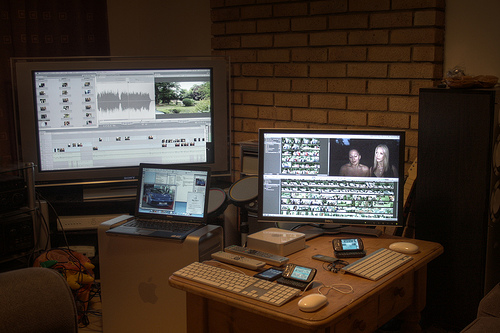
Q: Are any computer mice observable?
A: Yes, there is a computer mouse.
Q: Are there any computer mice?
A: Yes, there is a computer mouse.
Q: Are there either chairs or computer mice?
A: Yes, there is a computer mouse.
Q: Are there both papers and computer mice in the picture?
A: No, there is a computer mouse but no papers.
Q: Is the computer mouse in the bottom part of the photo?
A: Yes, the computer mouse is in the bottom of the image.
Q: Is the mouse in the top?
A: No, the mouse is in the bottom of the image.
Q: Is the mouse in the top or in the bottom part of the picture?
A: The mouse is in the bottom of the image.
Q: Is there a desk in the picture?
A: Yes, there is a desk.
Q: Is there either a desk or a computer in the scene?
A: Yes, there is a desk.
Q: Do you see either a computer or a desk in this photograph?
A: Yes, there is a desk.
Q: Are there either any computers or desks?
A: Yes, there is a desk.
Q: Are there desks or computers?
A: Yes, there is a desk.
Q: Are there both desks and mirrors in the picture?
A: No, there is a desk but no mirrors.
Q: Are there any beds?
A: No, there are no beds.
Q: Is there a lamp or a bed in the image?
A: No, there are no beds or lamps.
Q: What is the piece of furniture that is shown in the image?
A: The piece of furniture is a desk.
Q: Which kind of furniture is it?
A: The piece of furniture is a desk.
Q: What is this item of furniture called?
A: That is a desk.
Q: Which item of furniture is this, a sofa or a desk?
A: That is a desk.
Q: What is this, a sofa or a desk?
A: This is a desk.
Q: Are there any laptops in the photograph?
A: Yes, there is a laptop.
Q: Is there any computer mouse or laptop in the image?
A: Yes, there is a laptop.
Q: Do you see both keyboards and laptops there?
A: Yes, there are both a laptop and a keyboard.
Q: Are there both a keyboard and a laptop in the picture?
A: Yes, there are both a laptop and a keyboard.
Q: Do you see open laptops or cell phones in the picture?
A: Yes, there is an open laptop.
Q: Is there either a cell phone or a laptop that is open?
A: Yes, the laptop is open.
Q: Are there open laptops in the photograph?
A: Yes, there is an open laptop.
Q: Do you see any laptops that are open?
A: Yes, there is a laptop that is open.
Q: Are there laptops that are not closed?
A: Yes, there is a open laptop.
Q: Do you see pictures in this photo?
A: No, there are no pictures.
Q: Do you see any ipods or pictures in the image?
A: No, there are no pictures or ipods.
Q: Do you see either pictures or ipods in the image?
A: No, there are no pictures or ipods.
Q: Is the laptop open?
A: Yes, the laptop is open.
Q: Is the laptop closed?
A: No, the laptop is open.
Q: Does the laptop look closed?
A: No, the laptop is open.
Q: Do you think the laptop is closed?
A: No, the laptop is open.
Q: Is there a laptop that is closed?
A: No, there is a laptop but it is open.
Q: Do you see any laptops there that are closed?
A: No, there is a laptop but it is open.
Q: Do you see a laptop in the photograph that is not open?
A: No, there is a laptop but it is open.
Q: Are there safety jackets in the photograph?
A: No, there are no safety jackets.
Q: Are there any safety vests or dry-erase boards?
A: No, there are no safety vests or dry-erase boards.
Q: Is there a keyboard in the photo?
A: Yes, there is a keyboard.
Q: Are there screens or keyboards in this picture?
A: Yes, there is a keyboard.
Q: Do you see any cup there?
A: No, there are no cups.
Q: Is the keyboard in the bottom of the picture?
A: Yes, the keyboard is in the bottom of the image.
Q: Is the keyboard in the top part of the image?
A: No, the keyboard is in the bottom of the image.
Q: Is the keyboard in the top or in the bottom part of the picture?
A: The keyboard is in the bottom of the image.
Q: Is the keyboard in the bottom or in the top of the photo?
A: The keyboard is in the bottom of the image.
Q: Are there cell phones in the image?
A: Yes, there is a cell phone.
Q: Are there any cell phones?
A: Yes, there is a cell phone.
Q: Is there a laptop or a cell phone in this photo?
A: Yes, there is a cell phone.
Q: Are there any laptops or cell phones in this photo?
A: Yes, there is a cell phone.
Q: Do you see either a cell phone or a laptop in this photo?
A: Yes, there is a cell phone.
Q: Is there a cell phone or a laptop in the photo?
A: Yes, there is a cell phone.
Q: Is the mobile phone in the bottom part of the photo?
A: Yes, the mobile phone is in the bottom of the image.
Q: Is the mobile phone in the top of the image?
A: No, the mobile phone is in the bottom of the image.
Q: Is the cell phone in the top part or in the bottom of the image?
A: The cell phone is in the bottom of the image.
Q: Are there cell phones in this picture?
A: Yes, there is a cell phone.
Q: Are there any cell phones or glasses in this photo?
A: Yes, there is a cell phone.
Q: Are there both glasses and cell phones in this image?
A: No, there is a cell phone but no glasses.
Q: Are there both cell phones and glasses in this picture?
A: No, there is a cell phone but no glasses.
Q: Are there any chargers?
A: No, there are no chargers.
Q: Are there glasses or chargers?
A: No, there are no chargers or glasses.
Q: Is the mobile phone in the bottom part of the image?
A: Yes, the mobile phone is in the bottom of the image.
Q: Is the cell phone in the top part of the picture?
A: No, the cell phone is in the bottom of the image.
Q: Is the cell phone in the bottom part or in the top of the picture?
A: The cell phone is in the bottom of the image.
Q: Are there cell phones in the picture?
A: Yes, there is a cell phone.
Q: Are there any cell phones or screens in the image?
A: Yes, there is a cell phone.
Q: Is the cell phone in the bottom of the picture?
A: Yes, the cell phone is in the bottom of the image.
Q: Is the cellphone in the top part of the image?
A: No, the cellphone is in the bottom of the image.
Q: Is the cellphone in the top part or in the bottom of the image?
A: The cellphone is in the bottom of the image.